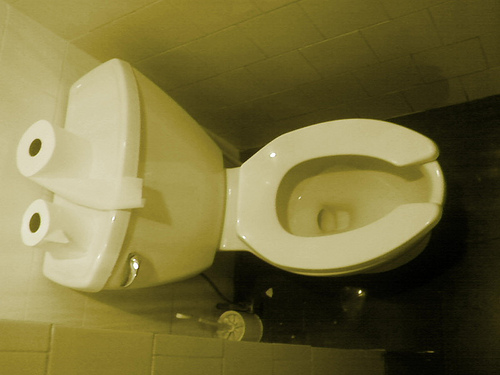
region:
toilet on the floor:
[22, 63, 442, 315]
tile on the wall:
[258, 9, 301, 49]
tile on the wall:
[420, 40, 464, 73]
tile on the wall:
[202, 34, 254, 71]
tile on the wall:
[419, 84, 453, 111]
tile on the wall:
[421, 48, 475, 73]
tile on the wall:
[323, 1, 372, 26]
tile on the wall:
[266, 10, 306, 48]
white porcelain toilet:
[28, 58, 455, 293]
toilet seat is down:
[231, 113, 443, 285]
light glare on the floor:
[353, 281, 366, 301]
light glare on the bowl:
[293, 190, 310, 207]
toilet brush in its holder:
[168, 302, 275, 346]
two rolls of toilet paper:
[7, 115, 159, 267]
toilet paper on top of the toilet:
[7, 113, 163, 289]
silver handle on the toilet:
[118, 253, 145, 288]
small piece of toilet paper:
[261, 283, 279, 299]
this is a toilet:
[10, 57, 478, 325]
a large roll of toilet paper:
[5, 116, 138, 201]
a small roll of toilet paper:
[12, 193, 104, 268]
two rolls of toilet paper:
[4, 113, 112, 264]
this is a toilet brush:
[153, 304, 280, 355]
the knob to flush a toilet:
[97, 242, 179, 312]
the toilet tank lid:
[12, 49, 159, 305]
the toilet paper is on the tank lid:
[13, 48, 150, 303]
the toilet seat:
[212, 80, 469, 283]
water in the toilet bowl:
[274, 175, 418, 240]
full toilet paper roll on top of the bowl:
[18, 128, 112, 185]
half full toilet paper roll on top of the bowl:
[12, 202, 88, 262]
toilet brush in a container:
[172, 303, 282, 348]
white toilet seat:
[233, 113, 452, 273]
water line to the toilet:
[213, 298, 263, 312]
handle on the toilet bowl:
[123, 255, 147, 282]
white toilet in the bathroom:
[58, 75, 494, 268]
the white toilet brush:
[163, 310, 260, 340]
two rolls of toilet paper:
[12, 120, 101, 260]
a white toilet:
[49, 77, 443, 289]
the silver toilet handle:
[121, 250, 153, 287]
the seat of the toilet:
[224, 148, 465, 249]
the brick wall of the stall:
[26, 318, 333, 372]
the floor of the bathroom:
[288, 293, 475, 338]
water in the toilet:
[289, 178, 371, 216]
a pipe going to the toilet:
[205, 265, 267, 322]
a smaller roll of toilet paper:
[19, 204, 88, 256]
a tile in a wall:
[64, 18, 152, 73]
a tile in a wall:
[137, 40, 209, 93]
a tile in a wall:
[178, 26, 268, 76]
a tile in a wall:
[299, 25, 373, 80]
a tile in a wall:
[360, 10, 445, 62]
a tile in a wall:
[405, 35, 485, 87]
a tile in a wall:
[388, 79, 467, 106]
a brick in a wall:
[3, 316, 53, 352]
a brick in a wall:
[0, 346, 50, 373]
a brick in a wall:
[41, 320, 151, 371]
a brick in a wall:
[148, 353, 223, 373]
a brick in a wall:
[272, 340, 311, 357]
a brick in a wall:
[269, 358, 308, 373]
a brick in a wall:
[311, 346, 344, 370]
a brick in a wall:
[248, 50, 319, 98]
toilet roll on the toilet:
[11, 119, 113, 191]